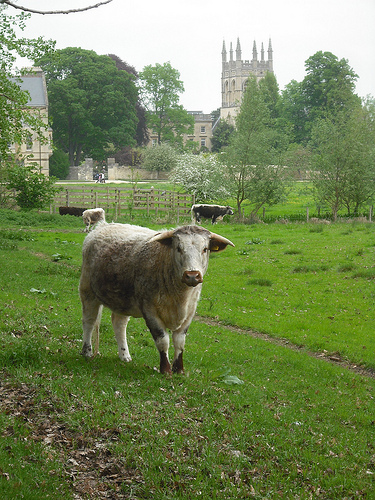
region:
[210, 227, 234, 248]
white horns on the cow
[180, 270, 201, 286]
the cow has a brown nose area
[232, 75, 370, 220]
tall trees on the border of the field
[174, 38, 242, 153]
an abbey across the field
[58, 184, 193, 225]
a wooden gate at the entrance to the field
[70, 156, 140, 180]
a concrete wall at the Abby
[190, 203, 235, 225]
a black and white cow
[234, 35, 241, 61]
a steeple on the top of the Abby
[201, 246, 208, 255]
the cows dark eyes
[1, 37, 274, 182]
the buildings in the distance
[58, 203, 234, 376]
the animals on the grass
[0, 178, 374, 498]
the green grass around animals and buildings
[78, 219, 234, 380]
the bull on the grass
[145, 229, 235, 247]
the horns on the bull's head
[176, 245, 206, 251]
the eyes on the bull's face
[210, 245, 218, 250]
the tag in the bull's ear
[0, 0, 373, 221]
the trees near the animals and buildings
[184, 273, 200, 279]
the nostril on the bull's face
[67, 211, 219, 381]
white cow in green field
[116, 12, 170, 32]
white clouds in blue sky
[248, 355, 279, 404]
short green and brown grass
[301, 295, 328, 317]
short green and brown grass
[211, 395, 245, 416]
short green and brown grass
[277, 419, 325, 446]
short green and brown grass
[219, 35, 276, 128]
old style tower in background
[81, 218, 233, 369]
animal facing the camera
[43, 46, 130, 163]
tall tree with dense green foliage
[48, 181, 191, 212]
wooden fence around grassland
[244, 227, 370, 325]
green lush grassland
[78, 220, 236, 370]
animal standing on grassland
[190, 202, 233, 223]
white and black animal in background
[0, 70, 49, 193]
building with dark roof in background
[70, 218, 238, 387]
A cow in a grassy pasture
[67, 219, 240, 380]
A cow in a grassy pasture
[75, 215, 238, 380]
A cow in a grassy pasture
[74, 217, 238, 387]
A cow in a grassy pasture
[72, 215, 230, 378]
a white and brown cow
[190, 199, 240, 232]
a black and white cow in a field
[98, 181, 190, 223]
a wood fence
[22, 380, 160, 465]
leaves on the ground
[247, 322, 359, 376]
a dirt path through a field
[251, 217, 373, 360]
a field of green grass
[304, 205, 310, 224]
a wood fence post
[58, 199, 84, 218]
two brown cows in a field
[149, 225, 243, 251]
a cow with horns on it's head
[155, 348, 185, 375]
a cow with two brown feet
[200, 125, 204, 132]
building has a window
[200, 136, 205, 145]
building has a window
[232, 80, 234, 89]
building has a window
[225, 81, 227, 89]
building has a window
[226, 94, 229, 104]
building has a window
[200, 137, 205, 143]
building has a window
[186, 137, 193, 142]
building has a window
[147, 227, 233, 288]
white cow with white horns and a brown nose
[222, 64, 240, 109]
two arched openings on belfry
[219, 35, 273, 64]
spires on top of a bell tower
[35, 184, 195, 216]
wooden fencing edging pasture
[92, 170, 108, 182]
people walk along the far walkway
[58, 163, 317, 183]
a stone fence along the road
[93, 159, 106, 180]
gated entry on the stone wall